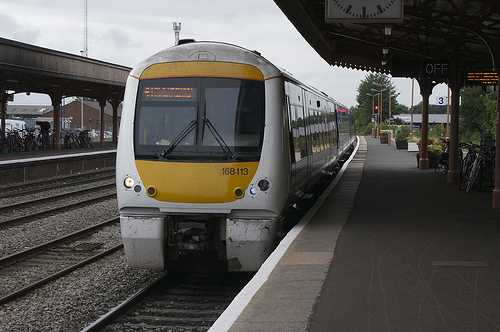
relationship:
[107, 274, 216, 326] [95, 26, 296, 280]
train tracks below train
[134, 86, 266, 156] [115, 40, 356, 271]
window on train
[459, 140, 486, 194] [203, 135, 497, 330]
bicycle on platform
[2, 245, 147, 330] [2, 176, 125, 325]
gravel beside tracks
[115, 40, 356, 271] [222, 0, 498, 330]
train at station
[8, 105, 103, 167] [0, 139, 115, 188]
bicycles parked on platform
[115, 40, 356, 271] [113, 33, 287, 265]
train has front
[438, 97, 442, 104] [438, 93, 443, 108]
number 3 has number 3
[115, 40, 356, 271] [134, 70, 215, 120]
train has marquee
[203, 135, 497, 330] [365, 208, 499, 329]
platform has scratches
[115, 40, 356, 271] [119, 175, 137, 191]
train has headlight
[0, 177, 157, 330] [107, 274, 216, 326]
gravel between train tracks